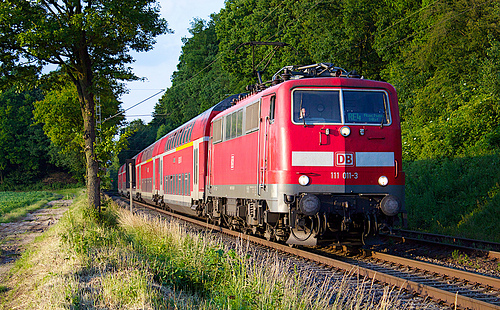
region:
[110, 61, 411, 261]
THE TRAIN IS LONG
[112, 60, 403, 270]
THE TRAIN IS RED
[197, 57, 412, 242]
THIS IS A TRAIN ENGINE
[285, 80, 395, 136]
THE TRAIN HAS A WINDSHIELD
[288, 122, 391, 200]
THE LIGHTS ARE ON THE FRONT OF THE TRAIN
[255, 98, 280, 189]
THE DOOR IS ON THE TRAIN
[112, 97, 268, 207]
THE TRAIN HAS MANY WINDOWS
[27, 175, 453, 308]
THE GRASS IS TALL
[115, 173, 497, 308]
THE TRACKS ARE LONG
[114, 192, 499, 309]
THE TRACKS ARE BROWN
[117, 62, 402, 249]
A red train traveling down a railroad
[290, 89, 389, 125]
The train's front windshield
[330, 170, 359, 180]
The train's registry number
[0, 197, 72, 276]
A crude dirt path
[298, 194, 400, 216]
Headlights on a train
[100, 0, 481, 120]
Electrical lines above a railroad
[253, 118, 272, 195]
Hand rails used to assist a person boarding the train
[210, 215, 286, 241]
A set of the train's wheels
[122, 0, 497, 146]
A dense forest flanking the railroad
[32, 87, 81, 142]
this is a branch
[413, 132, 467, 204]
this is a branch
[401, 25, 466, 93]
this is a branch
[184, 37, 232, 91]
this is a branch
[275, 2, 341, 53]
this is a branch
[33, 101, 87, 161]
this is a branch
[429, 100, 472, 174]
this is a branch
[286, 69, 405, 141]
the windshield on a train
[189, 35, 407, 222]
a big red train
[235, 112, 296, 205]
the door on a train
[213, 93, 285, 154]
the window on a train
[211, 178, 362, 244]
the wheels on a train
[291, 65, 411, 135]
the window on a train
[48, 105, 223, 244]
a tree near a train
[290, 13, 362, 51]
green leaves on a tree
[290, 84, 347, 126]
window of a train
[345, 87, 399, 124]
window of a train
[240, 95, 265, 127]
window of a train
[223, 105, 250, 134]
window of a train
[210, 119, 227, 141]
window of a train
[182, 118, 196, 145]
window of a train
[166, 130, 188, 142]
window of a train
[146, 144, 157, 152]
window of a train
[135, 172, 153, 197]
window of a train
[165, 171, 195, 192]
window of a train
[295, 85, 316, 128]
windshield wiper on the train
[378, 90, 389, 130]
windshield wiper on the train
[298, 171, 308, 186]
head light on the train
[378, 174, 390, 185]
head light on the train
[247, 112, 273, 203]
ladder on the train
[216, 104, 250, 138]
window on the train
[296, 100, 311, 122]
person sitting in the train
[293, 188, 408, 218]
bumper on the train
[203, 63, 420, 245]
locomotive is red and white